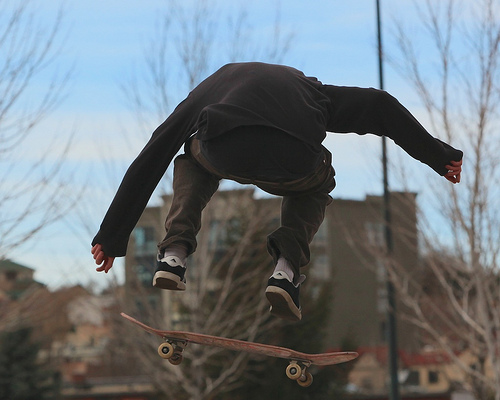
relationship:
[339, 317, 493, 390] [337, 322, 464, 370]
building with roof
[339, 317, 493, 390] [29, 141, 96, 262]
building in background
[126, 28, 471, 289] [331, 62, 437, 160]
skateboarder with arm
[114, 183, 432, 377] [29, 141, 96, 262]
building in background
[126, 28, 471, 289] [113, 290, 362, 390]
skateboarder above skateboard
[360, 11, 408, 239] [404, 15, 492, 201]
pole by tree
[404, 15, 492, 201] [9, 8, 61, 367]
tree in corner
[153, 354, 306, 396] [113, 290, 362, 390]
wheels on skateboard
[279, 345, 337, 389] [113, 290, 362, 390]
wheels on skateboard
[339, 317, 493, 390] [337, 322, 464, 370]
building has roof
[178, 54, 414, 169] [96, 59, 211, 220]
top has sleeves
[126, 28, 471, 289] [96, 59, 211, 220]
skateboarder wearing sleeves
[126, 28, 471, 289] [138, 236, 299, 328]
skateboarder wearing shoes